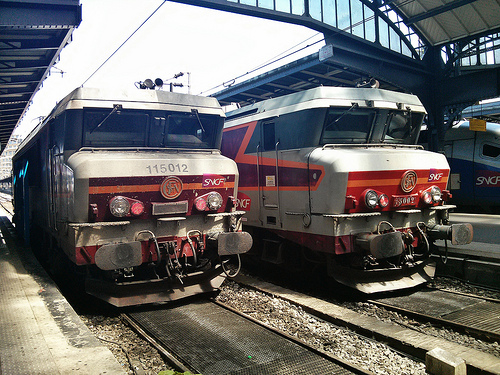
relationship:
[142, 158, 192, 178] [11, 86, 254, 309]
115012 on train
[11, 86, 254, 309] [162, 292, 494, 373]
train on tracks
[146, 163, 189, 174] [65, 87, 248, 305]
115012 on train front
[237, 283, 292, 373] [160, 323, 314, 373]
metal on tracks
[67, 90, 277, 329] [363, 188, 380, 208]
train front headlight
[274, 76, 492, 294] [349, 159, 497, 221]
train front headlight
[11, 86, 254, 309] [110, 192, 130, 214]
train front headlight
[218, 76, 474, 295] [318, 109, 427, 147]
train has windshield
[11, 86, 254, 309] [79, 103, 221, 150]
train has windshield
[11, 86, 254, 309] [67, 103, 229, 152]
train has windshield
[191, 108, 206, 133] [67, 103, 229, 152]
wiper on windshield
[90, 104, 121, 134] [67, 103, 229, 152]
wiper on windshield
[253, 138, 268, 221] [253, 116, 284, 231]
handle on side of door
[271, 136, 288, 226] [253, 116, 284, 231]
handle on side of door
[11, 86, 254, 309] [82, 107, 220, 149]
train has windshield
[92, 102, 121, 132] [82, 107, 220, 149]
wiper on windshield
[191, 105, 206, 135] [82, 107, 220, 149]
wiper on windshield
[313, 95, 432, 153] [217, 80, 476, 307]
windshield on train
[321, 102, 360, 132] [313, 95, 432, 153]
wipers on windshield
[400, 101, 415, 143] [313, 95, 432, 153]
wipers on windshield